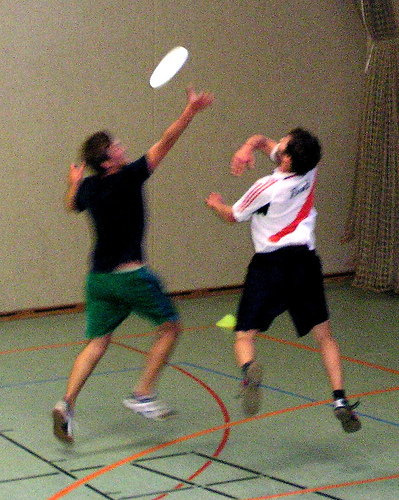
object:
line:
[132, 460, 200, 488]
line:
[46, 457, 63, 469]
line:
[88, 475, 105, 497]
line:
[0, 470, 59, 482]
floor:
[281, 424, 397, 497]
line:
[281, 387, 319, 448]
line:
[272, 398, 299, 419]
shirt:
[230, 167, 321, 251]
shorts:
[81, 264, 180, 338]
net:
[324, 59, 388, 289]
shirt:
[67, 152, 153, 273]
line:
[186, 433, 250, 497]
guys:
[52, 85, 213, 444]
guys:
[205, 128, 364, 432]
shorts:
[231, 246, 330, 337]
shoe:
[326, 385, 363, 431]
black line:
[0, 445, 55, 500]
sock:
[228, 361, 259, 378]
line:
[314, 488, 347, 498]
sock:
[329, 385, 346, 403]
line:
[127, 448, 195, 462]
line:
[132, 448, 198, 462]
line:
[117, 469, 259, 497]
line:
[0, 444, 195, 482]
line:
[0, 340, 44, 361]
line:
[133, 461, 233, 497]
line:
[193, 376, 218, 396]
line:
[68, 461, 104, 471]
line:
[306, 487, 343, 498]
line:
[118, 483, 135, 500]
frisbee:
[147, 42, 186, 87]